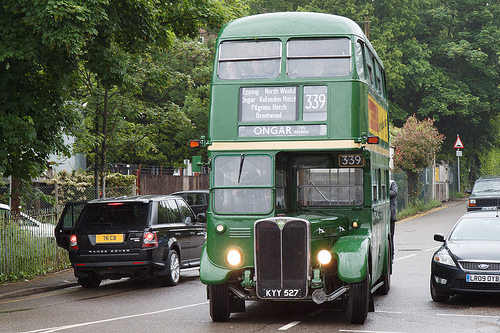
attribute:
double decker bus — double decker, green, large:
[189, 9, 391, 326]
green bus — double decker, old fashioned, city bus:
[190, 8, 391, 324]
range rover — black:
[53, 193, 205, 291]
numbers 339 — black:
[304, 94, 326, 110]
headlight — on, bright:
[225, 247, 245, 267]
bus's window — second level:
[218, 39, 282, 77]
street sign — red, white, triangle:
[451, 135, 465, 152]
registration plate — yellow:
[95, 233, 124, 243]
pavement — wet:
[1, 194, 498, 331]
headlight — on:
[314, 248, 332, 268]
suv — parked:
[45, 180, 196, 288]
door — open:
[49, 199, 89, 249]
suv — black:
[48, 189, 204, 289]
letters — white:
[245, 85, 301, 119]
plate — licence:
[93, 232, 125, 244]